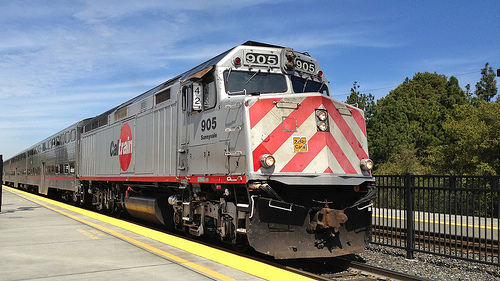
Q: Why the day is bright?
A: It's day time.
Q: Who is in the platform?
A: No one.